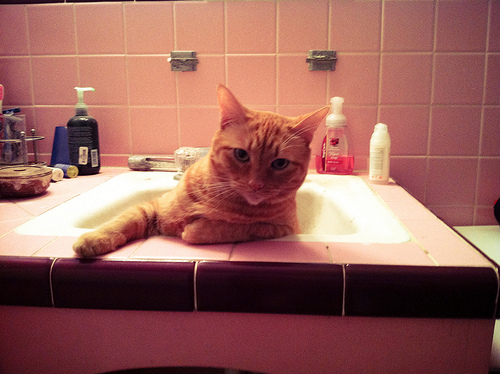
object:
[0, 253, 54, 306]
tile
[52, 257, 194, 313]
tile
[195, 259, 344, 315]
tile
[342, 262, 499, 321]
tile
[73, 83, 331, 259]
cat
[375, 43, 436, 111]
tile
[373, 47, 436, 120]
tile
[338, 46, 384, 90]
tile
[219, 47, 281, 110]
tile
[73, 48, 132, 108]
tile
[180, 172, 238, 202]
whiskers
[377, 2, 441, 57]
tile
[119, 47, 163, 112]
tile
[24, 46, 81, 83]
tile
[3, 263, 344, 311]
pink tile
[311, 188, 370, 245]
white sink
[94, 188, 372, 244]
sink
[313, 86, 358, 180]
soap bottle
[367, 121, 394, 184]
soap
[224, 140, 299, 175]
eyes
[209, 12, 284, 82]
tiles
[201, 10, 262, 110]
wall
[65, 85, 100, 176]
bottle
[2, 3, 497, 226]
wall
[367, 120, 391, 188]
bottle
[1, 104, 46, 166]
toothbrush holder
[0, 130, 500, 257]
counter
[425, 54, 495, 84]
tile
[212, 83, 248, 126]
ears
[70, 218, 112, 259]
paw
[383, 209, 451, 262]
tile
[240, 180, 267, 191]
nose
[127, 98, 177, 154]
tile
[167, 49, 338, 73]
towel holder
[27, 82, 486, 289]
inside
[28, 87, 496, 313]
sink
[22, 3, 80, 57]
tile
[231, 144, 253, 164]
eye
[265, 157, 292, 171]
eye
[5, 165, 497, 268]
counter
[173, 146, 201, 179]
faucet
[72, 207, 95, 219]
sink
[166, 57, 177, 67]
bolt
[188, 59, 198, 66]
bolt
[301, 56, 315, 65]
bolt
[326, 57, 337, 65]
bolt